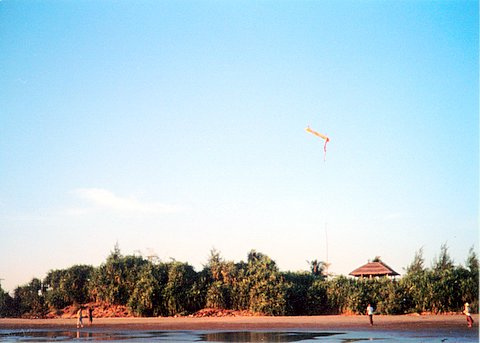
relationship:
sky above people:
[0, 1, 479, 274] [67, 297, 476, 329]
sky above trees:
[0, 1, 479, 274] [0, 242, 480, 313]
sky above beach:
[0, 1, 479, 274] [2, 315, 479, 329]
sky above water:
[0, 1, 479, 274] [2, 324, 477, 342]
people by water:
[67, 297, 476, 329] [2, 324, 477, 342]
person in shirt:
[360, 299, 378, 328] [366, 306, 373, 315]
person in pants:
[360, 299, 378, 328] [366, 313, 376, 323]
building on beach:
[343, 254, 400, 287] [2, 315, 479, 329]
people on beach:
[67, 297, 476, 329] [2, 315, 479, 329]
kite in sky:
[303, 123, 331, 155] [0, 1, 479, 274]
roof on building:
[345, 256, 398, 277] [343, 254, 400, 287]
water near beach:
[2, 324, 477, 342] [2, 315, 479, 329]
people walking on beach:
[67, 297, 476, 329] [2, 315, 479, 329]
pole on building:
[363, 273, 375, 280] [343, 254, 400, 287]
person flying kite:
[360, 299, 378, 328] [303, 123, 331, 155]